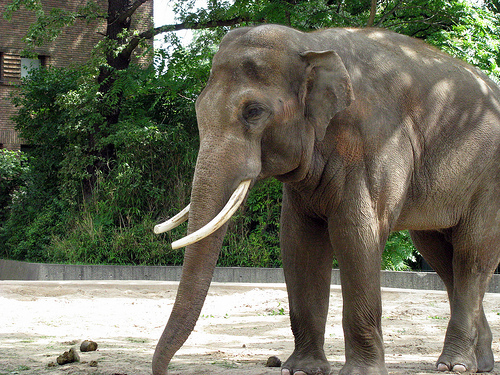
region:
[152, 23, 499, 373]
large grey elephant is standing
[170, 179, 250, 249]
long ivory colored left tusk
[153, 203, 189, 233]
ivory colored right tusk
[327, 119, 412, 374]
tall left front leg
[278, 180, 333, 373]
tall grey right front leg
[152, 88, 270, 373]
long grey elephant nose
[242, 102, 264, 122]
dark grey elephant eye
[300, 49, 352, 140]
floppy thin grey elephant ear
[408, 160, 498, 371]
tall grey rear elephant legs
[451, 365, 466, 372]
tiny white elephant toenail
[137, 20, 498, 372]
large elephant standing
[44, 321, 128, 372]
elephant poop on ground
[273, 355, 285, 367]
elephant poop on ground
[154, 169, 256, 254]
white elephant tusks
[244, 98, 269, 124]
large black eye of elephant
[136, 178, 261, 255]
ivory tusk of animal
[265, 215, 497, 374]
long thick legs of elephant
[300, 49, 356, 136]
large flappy ear of elephant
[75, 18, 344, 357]
head and trunk of elephant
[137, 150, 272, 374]
long grey trunk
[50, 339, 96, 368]
some elephant excrement on the ground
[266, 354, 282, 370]
some elephant excrement on the ground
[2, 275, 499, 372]
A small dirt field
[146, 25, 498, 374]
A large male elephant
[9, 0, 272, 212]
A large tree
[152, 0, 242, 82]
A clear blue sky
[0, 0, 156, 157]
A large brick building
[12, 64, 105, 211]
A large, full bush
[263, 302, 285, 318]
some leaves on the ground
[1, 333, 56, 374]
some grass on the ground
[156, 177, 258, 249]
Two white tusks on the elephant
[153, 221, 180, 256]
The tips of the elephant's tusks are broken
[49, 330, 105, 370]
A pile of dung on the ground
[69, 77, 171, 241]
Healthy green plants grow by the building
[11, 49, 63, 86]
A small window on the stone building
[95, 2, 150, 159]
A large brown tree behind the elephant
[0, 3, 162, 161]
An old stone building behind the tree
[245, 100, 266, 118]
The elephant's eye is open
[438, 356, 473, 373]
Two toes on the elephant's foot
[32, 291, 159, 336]
The sun is brightly shining on the dirt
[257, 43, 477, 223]
The elephant is gray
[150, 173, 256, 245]
Two elephant tusks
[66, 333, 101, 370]
The poop is brown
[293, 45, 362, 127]
The ears are large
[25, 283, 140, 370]
The ground is sand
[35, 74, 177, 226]
There is a tree in the background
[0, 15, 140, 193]
There is a brown building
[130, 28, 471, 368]
The elephant is standing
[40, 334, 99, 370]
There is poop on the ground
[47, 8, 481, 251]
Large bush in the background